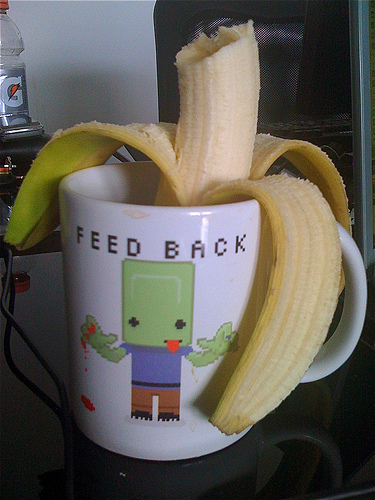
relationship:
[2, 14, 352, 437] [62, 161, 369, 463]
banana in mug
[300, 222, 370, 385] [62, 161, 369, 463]
handle on mug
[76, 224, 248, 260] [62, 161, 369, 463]
lettering on mug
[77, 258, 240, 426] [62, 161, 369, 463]
figure on mug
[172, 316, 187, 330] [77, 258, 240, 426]
eye on figure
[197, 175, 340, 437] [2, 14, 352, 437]
peel of banana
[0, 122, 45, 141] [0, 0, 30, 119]
phone by bottle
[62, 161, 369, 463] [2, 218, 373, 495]
mug on desk